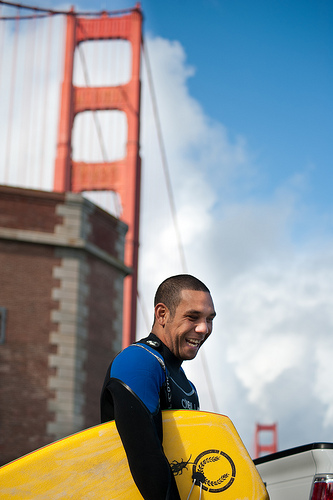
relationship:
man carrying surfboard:
[91, 259, 216, 411] [16, 422, 250, 499]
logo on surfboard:
[185, 451, 236, 498] [16, 422, 250, 499]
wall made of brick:
[6, 193, 118, 424] [25, 257, 53, 269]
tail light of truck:
[313, 476, 330, 499] [260, 449, 332, 498]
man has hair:
[91, 259, 216, 411] [162, 277, 211, 298]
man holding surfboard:
[91, 259, 216, 411] [16, 422, 250, 499]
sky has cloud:
[132, 3, 332, 267] [139, 33, 199, 164]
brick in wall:
[17, 365, 36, 380] [6, 193, 118, 424]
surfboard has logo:
[16, 422, 250, 499] [185, 451, 236, 498]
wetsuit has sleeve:
[112, 348, 172, 423] [113, 348, 169, 493]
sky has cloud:
[132, 3, 332, 267] [150, 196, 211, 270]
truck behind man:
[260, 449, 332, 498] [91, 259, 216, 411]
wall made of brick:
[6, 193, 118, 424] [91, 329, 103, 337]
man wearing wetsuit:
[91, 259, 216, 411] [112, 348, 172, 423]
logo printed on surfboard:
[185, 451, 236, 498] [16, 422, 250, 499]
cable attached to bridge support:
[145, 65, 182, 221] [69, 10, 132, 192]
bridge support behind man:
[69, 10, 132, 192] [91, 259, 216, 411]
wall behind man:
[6, 193, 118, 424] [91, 259, 216, 411]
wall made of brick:
[6, 193, 118, 424] [95, 361, 109, 370]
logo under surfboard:
[185, 451, 236, 498] [16, 422, 250, 499]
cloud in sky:
[139, 33, 199, 164] [132, 3, 332, 267]